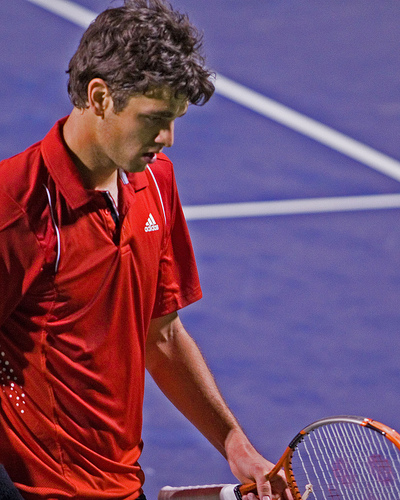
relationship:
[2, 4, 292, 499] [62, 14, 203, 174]
tennis player has head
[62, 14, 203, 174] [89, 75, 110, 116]
head has ear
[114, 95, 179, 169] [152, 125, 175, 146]
face has nose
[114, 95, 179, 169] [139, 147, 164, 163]
face has mouth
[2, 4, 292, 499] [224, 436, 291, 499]
tennis player has hand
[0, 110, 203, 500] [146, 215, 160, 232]
shirt has logo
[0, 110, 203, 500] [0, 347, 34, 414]
shirt has design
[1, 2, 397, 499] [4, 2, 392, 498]
tennis court made of turf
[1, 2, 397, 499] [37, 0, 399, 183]
tennis court has line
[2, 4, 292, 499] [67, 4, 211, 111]
tennis player has hair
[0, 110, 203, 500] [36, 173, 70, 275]
shirt has stripe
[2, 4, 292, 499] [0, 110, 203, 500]
tennis player wearing shirt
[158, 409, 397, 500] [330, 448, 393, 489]
tennis racket has design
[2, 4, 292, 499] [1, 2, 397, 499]
tennis player walking on tennis court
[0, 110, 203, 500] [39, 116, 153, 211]
shirt has collar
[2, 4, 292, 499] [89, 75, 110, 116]
tennis player has ear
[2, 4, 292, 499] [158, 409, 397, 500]
tennis player holding tennis racket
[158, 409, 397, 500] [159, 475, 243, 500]
tennis racket has handle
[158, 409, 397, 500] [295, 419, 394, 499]
tennis racket has strings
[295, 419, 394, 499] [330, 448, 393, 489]
strings have design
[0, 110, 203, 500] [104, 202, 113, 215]
shirt has button